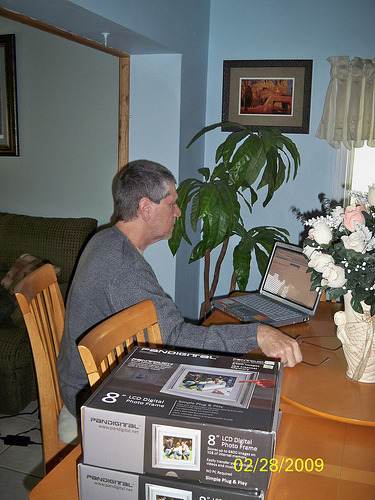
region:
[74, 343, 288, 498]
two boxes stacked on a table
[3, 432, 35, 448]
the battery of a laptop on the floor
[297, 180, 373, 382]
a bouquet of flowers on the table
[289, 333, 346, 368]
a pair of glasses on a lazy susan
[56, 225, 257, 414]
a gray shirt on a man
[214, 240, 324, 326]
a silver laptop on a table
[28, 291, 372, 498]
a light brown wood table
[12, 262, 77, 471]
a wooden chair in front of a table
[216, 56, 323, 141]
a framed picture on a wall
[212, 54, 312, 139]
artwork on the wall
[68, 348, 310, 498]
two boxes on the table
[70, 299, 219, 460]
chair pushed into the table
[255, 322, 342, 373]
hand holding glasses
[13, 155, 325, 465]
man sitting at the table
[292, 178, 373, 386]
flowers in a vase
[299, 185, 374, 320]
bouquet of pink and white flowers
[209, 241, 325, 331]
laptop on the table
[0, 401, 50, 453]
black cord on the ground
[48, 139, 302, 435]
this is a person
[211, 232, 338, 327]
this is a laptop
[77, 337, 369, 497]
this is a box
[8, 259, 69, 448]
this is a chair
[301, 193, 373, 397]
this is a flower vase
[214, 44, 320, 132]
this is a painting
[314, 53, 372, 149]
this is a curtain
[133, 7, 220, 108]
this is a wall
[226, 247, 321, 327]
the laptop is on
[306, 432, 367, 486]
the table surafe is brown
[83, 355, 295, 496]
the boxes are two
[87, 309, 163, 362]
the chair is wooden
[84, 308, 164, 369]
the chair is brown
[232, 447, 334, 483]
the photo was taken in 2009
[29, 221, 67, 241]
the sofa is brown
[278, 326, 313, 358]
glasses are on the table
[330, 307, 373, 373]
the vase is white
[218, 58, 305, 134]
picture is on the wall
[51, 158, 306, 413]
man sitting on chair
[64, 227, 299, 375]
gray crewneck sweatshirt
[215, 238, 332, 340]
silver laptop computer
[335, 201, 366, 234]
pink rose flower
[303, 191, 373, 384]
bouquet of flowers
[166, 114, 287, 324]
leafy green houseplant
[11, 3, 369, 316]
light blue wall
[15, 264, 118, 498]
wooden chair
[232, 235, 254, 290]
A leaf on a stem.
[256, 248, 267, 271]
A leaf on a stem.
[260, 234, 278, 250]
A leaf on a stem.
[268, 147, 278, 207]
A leaf on a stem.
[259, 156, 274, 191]
A leaf on a stem.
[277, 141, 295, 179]
A leaf on a stem.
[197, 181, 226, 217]
A leaf on a stem.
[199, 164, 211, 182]
A leaf on a stem.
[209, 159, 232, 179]
A leaf on a stem.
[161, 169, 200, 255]
A leaf on a stem.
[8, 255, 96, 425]
a brown wooden chair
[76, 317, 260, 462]
a box on top of the box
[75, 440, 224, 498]
a box on the top of the table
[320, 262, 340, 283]
a white rose on the vase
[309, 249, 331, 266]
a white rose on the vase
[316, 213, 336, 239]
a white rose on the vase